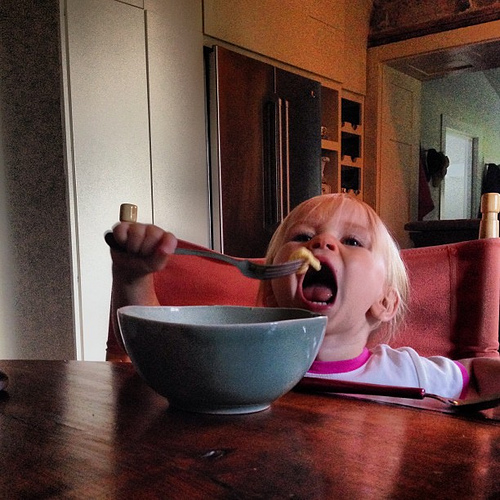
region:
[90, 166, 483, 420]
A child eating from a bowl of food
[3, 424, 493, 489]
A brown wooden table surface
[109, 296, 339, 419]
A blue ceramic bowl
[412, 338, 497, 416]
A child's left arm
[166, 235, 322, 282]
A fork with food on it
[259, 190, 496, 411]
A child wearing a pink and white shirt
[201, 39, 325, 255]
A stainless steel refrigerator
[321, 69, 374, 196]
An area of shelves in the background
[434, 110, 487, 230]
A doorway in the background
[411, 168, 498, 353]
Part of a wooden and fabric chair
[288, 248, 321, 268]
yellow elbow maccoroni and cheese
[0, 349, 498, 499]
a dark and shiny brown wooden table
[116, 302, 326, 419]
a big white bowl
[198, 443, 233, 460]
a dark knot in a wooden table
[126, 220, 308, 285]
a silver fork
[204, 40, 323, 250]
a brown double fridge doors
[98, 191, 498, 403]
a little girl eating maccoroni and cheese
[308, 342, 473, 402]
part of a little girls white and pink shirt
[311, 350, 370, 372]
a pink collar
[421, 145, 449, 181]
a brown hat hanging on a hat hook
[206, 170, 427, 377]
a kid with his mouth open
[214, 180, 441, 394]
a kid open wide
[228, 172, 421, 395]
little boy open wide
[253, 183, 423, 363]
little boy with mouth open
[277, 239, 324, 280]
food on a fork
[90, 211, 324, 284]
fork in a right hand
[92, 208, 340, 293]
fork in boy's right hand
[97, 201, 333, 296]
fork in toddler's right hand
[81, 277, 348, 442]
large ceramic bowl on table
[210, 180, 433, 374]
a blond haired toddler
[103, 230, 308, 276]
A silver fork a child is eating with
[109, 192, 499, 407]
A blonde girl eating.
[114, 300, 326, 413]
A shiny blue bowl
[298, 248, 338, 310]
Open mouth of a girl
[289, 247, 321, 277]
Piece of tan food on a child's fork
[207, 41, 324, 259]
Silver double door fridge.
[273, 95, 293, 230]
Two silver long handles of a fridge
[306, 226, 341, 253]
Nose on a blonde child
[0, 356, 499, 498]
Dark brown table a child is eating at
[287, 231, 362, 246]
Dark eyes of a blonde child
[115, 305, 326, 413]
Gray bowl sitting on the table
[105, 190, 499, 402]
Young kid eating with a fork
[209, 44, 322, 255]
a metal refrigerator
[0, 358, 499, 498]
a dark wooden table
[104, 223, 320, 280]
metal fork with food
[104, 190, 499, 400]
the kid is sitting on a red chair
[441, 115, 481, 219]
window with white curtains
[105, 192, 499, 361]
chair made of red cloth and wooden frame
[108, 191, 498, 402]
kid with blond hair eating breakfast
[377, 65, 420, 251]
white wooden door